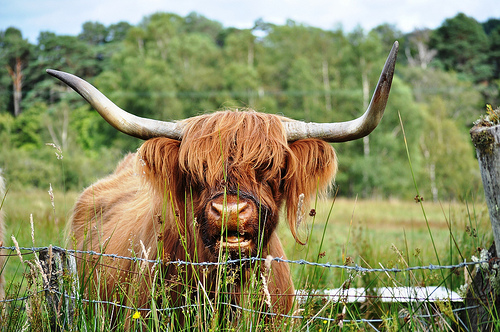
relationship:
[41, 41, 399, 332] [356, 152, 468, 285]
cow standing in a field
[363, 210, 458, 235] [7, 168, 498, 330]
dirt patch in field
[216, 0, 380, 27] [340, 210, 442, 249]
skies over field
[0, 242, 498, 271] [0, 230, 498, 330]
barbed wire of fence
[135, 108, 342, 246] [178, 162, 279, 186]
hair covring eyes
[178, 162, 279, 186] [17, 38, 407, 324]
eyes of a cow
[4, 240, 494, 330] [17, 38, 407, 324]
fence in front of a cow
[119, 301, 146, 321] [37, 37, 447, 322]
flower growing in front of a cow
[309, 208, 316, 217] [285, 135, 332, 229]
dot coming down from ear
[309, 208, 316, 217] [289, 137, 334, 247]
dot coming down from ear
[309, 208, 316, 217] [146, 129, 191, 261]
dot coming down from ear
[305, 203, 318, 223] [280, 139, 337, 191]
dot on ear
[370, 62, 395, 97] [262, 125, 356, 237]
dot on ear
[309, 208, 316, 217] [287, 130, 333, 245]
dot on ear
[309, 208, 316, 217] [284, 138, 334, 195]
dot on ear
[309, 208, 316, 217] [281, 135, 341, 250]
dot on ear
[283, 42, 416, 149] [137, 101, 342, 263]
horn on cow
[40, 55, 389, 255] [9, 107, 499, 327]
cow standing in field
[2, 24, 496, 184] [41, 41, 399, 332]
trees are behind cow